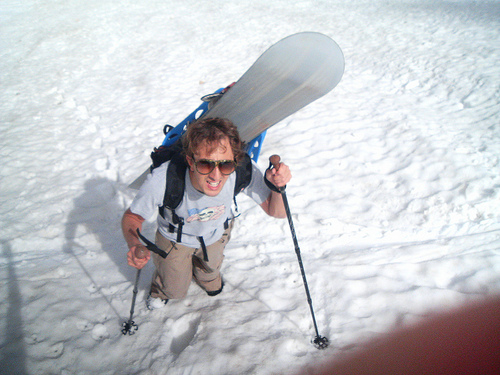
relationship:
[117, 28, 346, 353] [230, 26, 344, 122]
man with a snowboard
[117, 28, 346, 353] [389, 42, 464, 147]
man on snow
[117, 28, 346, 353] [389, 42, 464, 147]
man walking on snow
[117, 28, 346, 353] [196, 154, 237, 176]
man wearing sunglasses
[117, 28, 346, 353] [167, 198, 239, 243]
man wearing blue shirt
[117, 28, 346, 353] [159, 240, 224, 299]
man wearing pants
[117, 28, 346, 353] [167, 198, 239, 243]
man wearing a shirt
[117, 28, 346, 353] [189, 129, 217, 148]
man has hair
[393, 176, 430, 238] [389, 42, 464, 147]
ground has snow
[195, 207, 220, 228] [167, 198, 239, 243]
skull on mans shirt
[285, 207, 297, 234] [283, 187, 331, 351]
black ski pole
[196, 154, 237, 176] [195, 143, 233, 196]
sunglasses on mans face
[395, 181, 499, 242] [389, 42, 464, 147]
footprints in snow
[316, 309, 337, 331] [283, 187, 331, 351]
track from pole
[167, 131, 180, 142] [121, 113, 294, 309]
blue equipment on man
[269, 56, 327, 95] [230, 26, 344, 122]
striped design on snowboard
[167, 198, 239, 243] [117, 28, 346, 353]
shirt on man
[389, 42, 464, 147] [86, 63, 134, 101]
snow clear and white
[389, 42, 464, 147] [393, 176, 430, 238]
snow on ground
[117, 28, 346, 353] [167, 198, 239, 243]
man wearing grey shirt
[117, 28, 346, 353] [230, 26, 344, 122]
man carrying a snowboard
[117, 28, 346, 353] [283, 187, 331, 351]
man holding pole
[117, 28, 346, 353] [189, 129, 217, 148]
man with brown hair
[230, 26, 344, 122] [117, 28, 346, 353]
snowboard on man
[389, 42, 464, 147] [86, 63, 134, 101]
snow on ground white